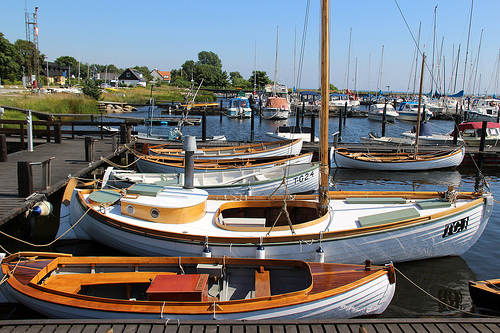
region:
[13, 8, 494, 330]
a mariner on a lake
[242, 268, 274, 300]
a wooden bench on a boat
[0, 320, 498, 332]
a wooden dock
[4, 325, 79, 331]
several wooden planks in the dock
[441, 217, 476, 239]
a black and white sign on a boat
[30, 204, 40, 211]
a blue pointy end on a reel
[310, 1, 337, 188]
a rusty metal pole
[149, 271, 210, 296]
a red wooden box in the boat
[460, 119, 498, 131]
a burgundy cover over a boat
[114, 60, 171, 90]
houses in the background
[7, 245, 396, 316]
boat first in harbor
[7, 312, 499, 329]
pier beside first boat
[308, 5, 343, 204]
mast of second boat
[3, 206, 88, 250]
rope tying second boat to dock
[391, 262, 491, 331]
rope tying first boat to dock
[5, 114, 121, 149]
brown railing along dock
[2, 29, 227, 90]
trees behind houses on shore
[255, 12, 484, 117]
masts of boats in background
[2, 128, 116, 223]
brown walkway of dock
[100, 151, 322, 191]
third boat in line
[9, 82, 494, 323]
numerous boats in a harbor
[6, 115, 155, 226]
grey wooden dock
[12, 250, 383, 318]
wooden boat painted white on the bottom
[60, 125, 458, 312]
group of small sailoats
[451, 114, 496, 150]
boat with a maroon cover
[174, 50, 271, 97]
tall dark green trees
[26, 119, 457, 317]
boats tied to a dock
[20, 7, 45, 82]
tall metal tower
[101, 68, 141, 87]
black and white house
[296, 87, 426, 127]
white and blue boats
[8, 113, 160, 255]
A dock beside boats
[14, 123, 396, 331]
Boats docked beside each other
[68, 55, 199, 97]
Houses in the distance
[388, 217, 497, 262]
TG1 written on boat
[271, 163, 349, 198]
TG24 written on boat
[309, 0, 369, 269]
Brown pole on boat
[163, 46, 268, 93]
Trees in the distance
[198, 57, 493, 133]
Many boats in the distance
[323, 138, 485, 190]
Boat sitting in water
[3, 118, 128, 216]
Dock is brown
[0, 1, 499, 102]
a clear blue sky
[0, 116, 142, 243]
a wooden pier with boats docked to it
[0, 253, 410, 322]
a small wooden fishing boat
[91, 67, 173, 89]
a couple of houses along the waters edge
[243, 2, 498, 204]
poles for the boat sails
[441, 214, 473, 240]
TGI painted on the side of the boat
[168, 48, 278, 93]
a bunch of trees on the land behind the river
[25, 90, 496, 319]
a river with a lot of boats docked near the shore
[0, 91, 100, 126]
overgrown grass on the river bank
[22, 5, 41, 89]
a metal tower in front of the trees